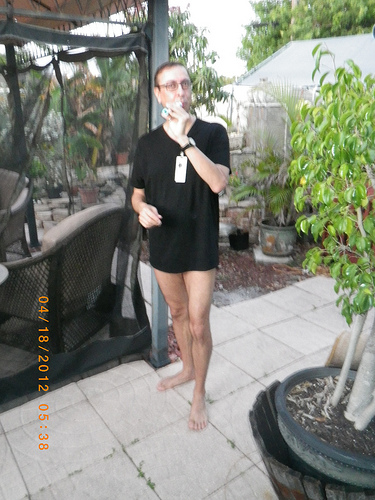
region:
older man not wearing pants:
[129, 61, 233, 433]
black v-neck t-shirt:
[126, 117, 233, 273]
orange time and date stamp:
[35, 293, 50, 451]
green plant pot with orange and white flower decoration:
[255, 213, 299, 256]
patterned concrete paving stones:
[0, 223, 373, 497]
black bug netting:
[0, 23, 152, 403]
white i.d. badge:
[171, 149, 189, 185]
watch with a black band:
[178, 133, 196, 151]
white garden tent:
[223, 32, 373, 169]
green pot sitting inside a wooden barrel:
[272, 362, 374, 489]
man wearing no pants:
[128, 64, 253, 429]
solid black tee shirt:
[121, 117, 252, 272]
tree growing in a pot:
[254, 60, 372, 465]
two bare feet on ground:
[152, 364, 218, 429]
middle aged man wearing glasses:
[155, 53, 210, 123]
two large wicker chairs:
[4, 160, 133, 361]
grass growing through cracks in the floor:
[106, 435, 163, 499]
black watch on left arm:
[180, 135, 200, 151]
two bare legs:
[145, 265, 221, 439]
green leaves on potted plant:
[305, 106, 365, 232]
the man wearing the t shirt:
[129, 55, 253, 442]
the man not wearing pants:
[139, 264, 234, 440]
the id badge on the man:
[171, 148, 192, 187]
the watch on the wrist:
[177, 128, 203, 157]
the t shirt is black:
[106, 118, 246, 285]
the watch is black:
[173, 126, 201, 157]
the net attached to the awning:
[0, 27, 156, 370]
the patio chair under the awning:
[0, 167, 132, 338]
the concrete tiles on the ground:
[46, 407, 189, 494]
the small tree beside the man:
[275, 61, 374, 440]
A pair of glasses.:
[157, 76, 196, 89]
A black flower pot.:
[228, 229, 251, 252]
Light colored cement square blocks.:
[0, 274, 373, 499]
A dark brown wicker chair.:
[0, 198, 132, 357]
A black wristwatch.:
[178, 136, 197, 153]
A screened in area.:
[5, 19, 160, 410]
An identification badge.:
[171, 146, 189, 184]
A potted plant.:
[231, 144, 304, 260]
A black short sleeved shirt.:
[123, 117, 233, 273]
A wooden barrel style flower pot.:
[249, 378, 373, 499]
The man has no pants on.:
[152, 253, 218, 418]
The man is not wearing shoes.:
[161, 366, 217, 429]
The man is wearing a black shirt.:
[128, 122, 244, 274]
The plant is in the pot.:
[281, 346, 372, 479]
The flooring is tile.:
[73, 394, 177, 473]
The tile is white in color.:
[86, 417, 177, 479]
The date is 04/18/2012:
[34, 291, 52, 397]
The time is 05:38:
[36, 397, 55, 453]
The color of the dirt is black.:
[304, 409, 360, 450]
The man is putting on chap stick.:
[155, 96, 196, 127]